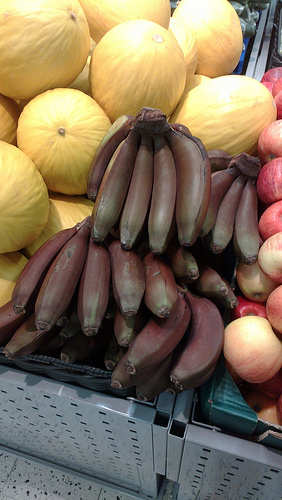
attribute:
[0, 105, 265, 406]
bananas — brown, red, green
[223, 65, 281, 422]
apples — red, here, ripe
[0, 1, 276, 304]
melons — yellow, here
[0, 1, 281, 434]
fruit — circular, cream colored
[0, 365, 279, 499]
bins — metal, silver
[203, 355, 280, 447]
box — green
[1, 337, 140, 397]
basket — black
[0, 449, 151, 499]
tile — white with black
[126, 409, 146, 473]
holes — little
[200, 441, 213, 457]
hole — spotted, black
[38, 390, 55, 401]
hole — black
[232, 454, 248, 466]
hole — black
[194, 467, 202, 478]
hole — black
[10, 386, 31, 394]
hole — black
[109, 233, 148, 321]
banana — here, brown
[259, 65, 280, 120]
apple — here, ripe, red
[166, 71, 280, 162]
squash — yellow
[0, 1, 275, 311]
squash — here